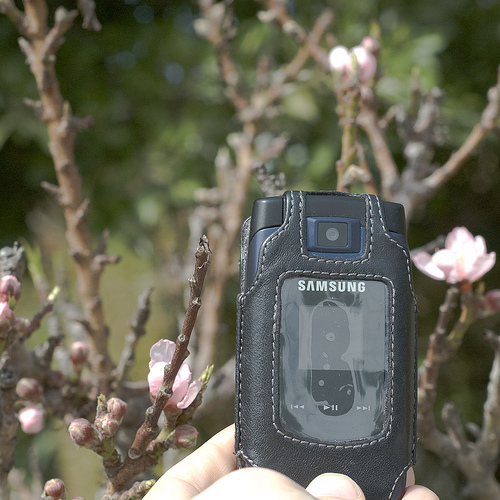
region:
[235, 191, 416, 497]
Someone is holding up a phone.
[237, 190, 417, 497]
Blue and black Samsung phone.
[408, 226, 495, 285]
Large pink flower to the right of phone.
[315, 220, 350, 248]
Phone has a camera on it.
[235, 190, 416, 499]
A blue and black phone in a case.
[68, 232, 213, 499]
One branch is in focus.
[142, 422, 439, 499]
Hand that is holding the phone.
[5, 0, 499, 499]
Blooming tree behing the phone.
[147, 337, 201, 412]
Pink flower to the left of the phone.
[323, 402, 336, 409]
Play button on the front of the phone.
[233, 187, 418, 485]
a black and blue cellphone the person is holding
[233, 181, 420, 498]
a cellphone on a black case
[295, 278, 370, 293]
a SAMSUNG print on the cellphone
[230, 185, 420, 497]
a samsung cell phone the person is holding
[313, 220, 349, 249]
a built-in camera of the cell phone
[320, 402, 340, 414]
a play and pause sign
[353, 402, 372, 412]
a forward sign on the cell phone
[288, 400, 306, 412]
a rewind sign on the cellphone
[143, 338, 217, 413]
a flower on the background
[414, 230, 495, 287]
a flower on the background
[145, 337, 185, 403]
pink petal on branch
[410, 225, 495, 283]
pink petal on branch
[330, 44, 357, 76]
pink petal on branch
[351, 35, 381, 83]
pink petal on branch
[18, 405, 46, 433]
pink petal on branch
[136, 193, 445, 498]
black phone in hand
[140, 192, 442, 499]
hand holding blue and black phone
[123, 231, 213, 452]
branch is next to branch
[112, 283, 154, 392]
branch is next to branch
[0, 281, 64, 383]
branch is next to branch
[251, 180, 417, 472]
A person holding a cellphone.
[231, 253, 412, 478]
A case over the cellphone.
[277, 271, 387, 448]
Front of the case is plastic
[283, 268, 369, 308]
Samsung name in front of the case.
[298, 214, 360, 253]
Camera of the phone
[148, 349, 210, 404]
Pink flower on the branch.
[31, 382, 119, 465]
Flower buds on the branch.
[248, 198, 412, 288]
The cellphone is blue and black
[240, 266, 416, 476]
The case is trimmed in white thread.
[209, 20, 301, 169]
Tree branches in the background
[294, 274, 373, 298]
samsung written in white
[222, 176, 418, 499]
a cell phone in a case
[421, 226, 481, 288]
a pink flower bud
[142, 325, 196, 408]
a pink flower bud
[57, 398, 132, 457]
two unopened flower buds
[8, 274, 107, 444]
branches with flower buds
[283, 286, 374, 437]
clear front of a phone case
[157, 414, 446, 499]
fingers holding a cell phone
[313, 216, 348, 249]
camera lense on a cell phone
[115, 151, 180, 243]
green foliage on a tree